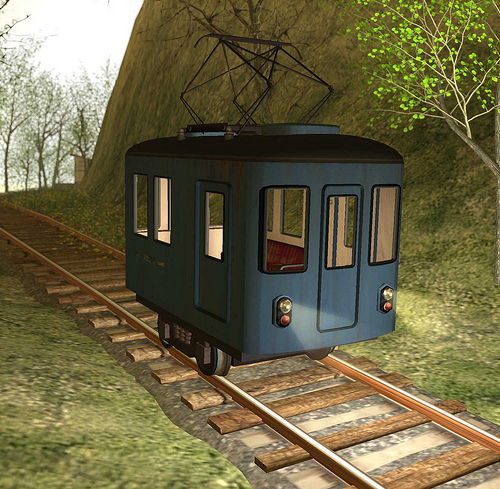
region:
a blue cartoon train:
[82, 103, 428, 433]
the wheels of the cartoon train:
[148, 303, 248, 390]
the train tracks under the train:
[183, 370, 449, 482]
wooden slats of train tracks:
[259, 408, 484, 463]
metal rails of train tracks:
[203, 374, 380, 477]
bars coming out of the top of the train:
[160, 8, 322, 165]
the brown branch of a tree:
[366, 7, 498, 171]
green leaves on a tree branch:
[356, 12, 479, 137]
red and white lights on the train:
[265, 293, 326, 349]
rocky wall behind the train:
[62, 23, 492, 207]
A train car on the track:
[127, 131, 404, 349]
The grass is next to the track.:
[33, 358, 138, 460]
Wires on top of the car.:
[186, 2, 320, 119]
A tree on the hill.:
[376, 23, 479, 155]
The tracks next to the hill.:
[389, 255, 487, 476]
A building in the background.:
[55, 133, 99, 195]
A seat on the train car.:
[226, 207, 317, 276]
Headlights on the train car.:
[271, 283, 402, 311]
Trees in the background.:
[12, 72, 79, 180]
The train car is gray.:
[116, 125, 398, 347]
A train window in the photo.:
[262, 187, 304, 274]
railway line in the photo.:
[272, 389, 433, 467]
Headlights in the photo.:
[277, 296, 292, 318]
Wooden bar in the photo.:
[296, 382, 351, 422]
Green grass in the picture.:
[2, 389, 151, 474]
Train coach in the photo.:
[162, 133, 402, 366]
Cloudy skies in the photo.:
[45, 2, 122, 64]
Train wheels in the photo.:
[156, 320, 233, 373]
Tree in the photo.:
[392, 14, 498, 141]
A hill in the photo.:
[115, 25, 188, 123]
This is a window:
[252, 179, 316, 284]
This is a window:
[320, 178, 362, 275]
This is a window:
[368, 176, 402, 283]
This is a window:
[195, 172, 242, 272]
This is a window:
[148, 171, 176, 248]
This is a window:
[131, 169, 152, 240]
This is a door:
[318, 176, 362, 328]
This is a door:
[188, 158, 235, 338]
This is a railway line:
[4, 202, 496, 484]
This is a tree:
[398, 8, 496, 195]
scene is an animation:
[0, 2, 493, 472]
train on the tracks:
[78, 87, 426, 352]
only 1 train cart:
[132, 96, 407, 378]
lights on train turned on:
[253, 266, 412, 355]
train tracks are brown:
[0, 201, 488, 483]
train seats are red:
[270, 230, 318, 278]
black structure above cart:
[170, 7, 344, 134]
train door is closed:
[186, 169, 231, 325]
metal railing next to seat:
[273, 253, 308, 281]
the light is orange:
[273, 305, 300, 330]